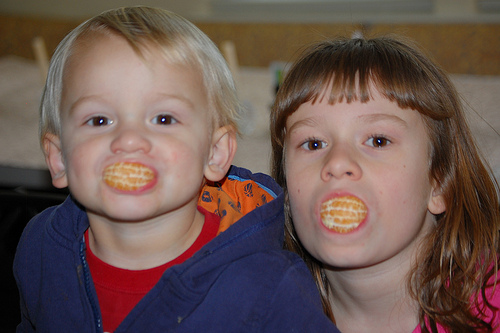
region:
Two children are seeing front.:
[56, 59, 439, 299]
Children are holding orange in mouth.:
[94, 141, 386, 250]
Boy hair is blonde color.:
[60, 15, 227, 65]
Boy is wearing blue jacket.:
[30, 248, 277, 323]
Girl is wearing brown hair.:
[323, 52, 468, 135]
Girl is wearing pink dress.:
[402, 244, 488, 331]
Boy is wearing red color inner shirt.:
[42, 213, 172, 320]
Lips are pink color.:
[95, 145, 387, 257]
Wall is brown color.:
[403, 9, 486, 74]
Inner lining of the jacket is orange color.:
[207, 185, 266, 225]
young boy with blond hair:
[20, 3, 247, 228]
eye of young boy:
[78, 116, 115, 130]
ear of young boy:
[205, 118, 244, 183]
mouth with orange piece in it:
[91, 158, 167, 197]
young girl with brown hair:
[261, 32, 495, 319]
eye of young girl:
[293, 128, 328, 157]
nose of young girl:
[319, 145, 370, 184]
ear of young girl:
[422, 154, 461, 216]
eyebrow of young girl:
[357, 106, 407, 127]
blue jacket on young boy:
[12, 183, 281, 330]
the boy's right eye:
[75, 107, 117, 135]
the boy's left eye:
[140, 103, 183, 130]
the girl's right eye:
[292, 129, 329, 154]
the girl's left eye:
[355, 125, 399, 152]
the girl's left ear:
[423, 145, 458, 216]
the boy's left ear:
[203, 110, 239, 186]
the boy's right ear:
[31, 124, 74, 191]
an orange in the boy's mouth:
[97, 155, 161, 196]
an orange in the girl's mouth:
[313, 185, 372, 238]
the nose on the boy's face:
[107, 96, 152, 155]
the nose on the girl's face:
[315, 117, 360, 183]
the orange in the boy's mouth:
[95, 157, 163, 196]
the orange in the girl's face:
[315, 186, 373, 235]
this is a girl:
[270, 23, 425, 326]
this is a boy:
[32, 10, 274, 274]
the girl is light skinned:
[379, 170, 406, 220]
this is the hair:
[415, 66, 459, 118]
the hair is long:
[423, 226, 456, 296]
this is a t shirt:
[106, 265, 139, 304]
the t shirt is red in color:
[98, 270, 136, 299]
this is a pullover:
[183, 274, 273, 323]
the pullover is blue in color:
[189, 288, 266, 331]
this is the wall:
[229, 12, 304, 54]